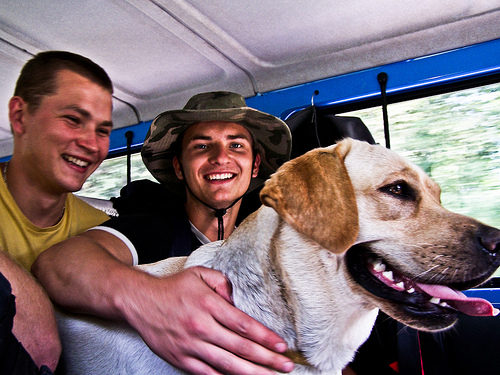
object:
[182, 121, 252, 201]
face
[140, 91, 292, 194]
hat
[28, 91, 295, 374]
man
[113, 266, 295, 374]
hand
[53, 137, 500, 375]
dog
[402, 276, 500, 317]
tongue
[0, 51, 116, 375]
man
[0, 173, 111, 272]
shirt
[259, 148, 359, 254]
ear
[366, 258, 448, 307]
teeth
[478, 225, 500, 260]
nose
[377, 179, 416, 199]
eye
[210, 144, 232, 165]
nose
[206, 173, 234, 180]
teeth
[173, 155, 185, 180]
ear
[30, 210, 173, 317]
arm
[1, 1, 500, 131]
ceiling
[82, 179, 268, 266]
shirt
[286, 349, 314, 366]
collar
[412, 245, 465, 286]
whiskers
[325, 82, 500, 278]
window